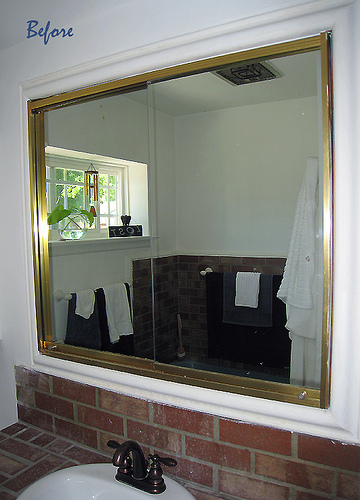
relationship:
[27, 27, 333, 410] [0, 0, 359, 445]
mirror on wall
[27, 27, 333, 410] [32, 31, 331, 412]
mirror has golden border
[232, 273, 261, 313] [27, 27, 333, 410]
towel reflected on mirror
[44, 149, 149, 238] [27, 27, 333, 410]
window reflected on mirror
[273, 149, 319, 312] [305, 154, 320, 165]
bath cloth hanging from hanger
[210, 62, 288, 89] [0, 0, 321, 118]
extractor fan on ceiling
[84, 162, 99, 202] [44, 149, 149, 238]
wind chimes hanging in window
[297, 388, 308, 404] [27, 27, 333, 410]
screw in mirror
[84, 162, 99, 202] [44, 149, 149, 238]
wind chimes hanging at window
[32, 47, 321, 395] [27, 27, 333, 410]
reflection of room in mirror